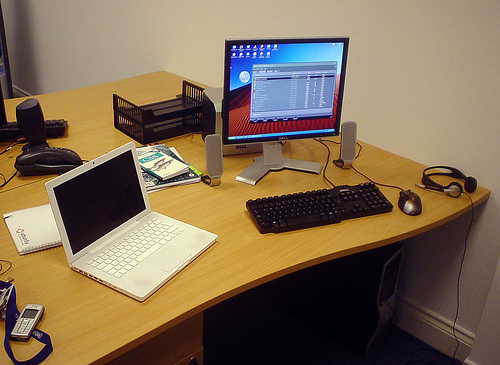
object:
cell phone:
[11, 304, 44, 341]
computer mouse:
[399, 189, 422, 217]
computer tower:
[220, 36, 350, 186]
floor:
[252, 328, 351, 365]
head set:
[414, 163, 478, 198]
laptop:
[42, 141, 219, 303]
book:
[119, 142, 203, 193]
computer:
[217, 35, 347, 145]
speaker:
[201, 133, 224, 186]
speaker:
[332, 121, 358, 172]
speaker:
[15, 96, 50, 153]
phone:
[12, 146, 86, 178]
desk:
[0, 69, 491, 365]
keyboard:
[245, 181, 394, 235]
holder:
[113, 79, 216, 145]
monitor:
[223, 42, 343, 140]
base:
[234, 141, 324, 186]